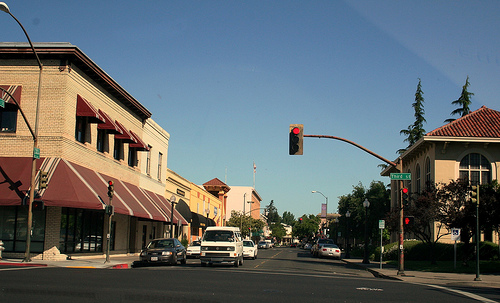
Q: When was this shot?
A: Daytime.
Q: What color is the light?
A: Red.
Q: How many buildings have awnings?
A: 1.